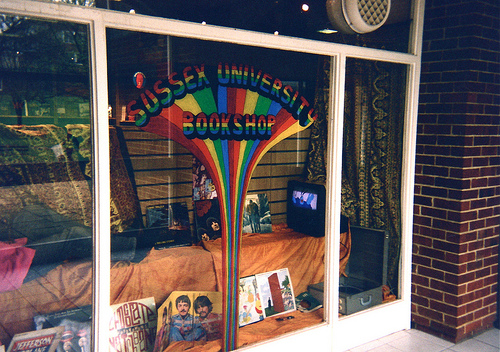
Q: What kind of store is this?
A: A bookshop.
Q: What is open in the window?
A: A small black box.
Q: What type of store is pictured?
A: Bookshop.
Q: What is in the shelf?
A: Books.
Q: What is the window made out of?
A: Glass.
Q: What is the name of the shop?
A: Sussex University.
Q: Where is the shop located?
A: Sussex.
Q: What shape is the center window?
A: Square.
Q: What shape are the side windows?
A: Rectangles.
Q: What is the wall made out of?
A: Brick.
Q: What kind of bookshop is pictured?
A: University bookshop.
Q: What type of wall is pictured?
A: Brick.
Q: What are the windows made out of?
A: Glass.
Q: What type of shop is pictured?
A: Bookshop.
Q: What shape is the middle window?
A: Square.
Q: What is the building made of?
A: Bricks.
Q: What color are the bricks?
A: Red.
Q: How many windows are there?
A: Three.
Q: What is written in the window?
A: Sussex University Bookshop.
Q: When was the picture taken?
A: Daytime.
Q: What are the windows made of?
A: Glass.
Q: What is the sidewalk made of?
A: Cement.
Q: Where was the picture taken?
A: At the storefront.